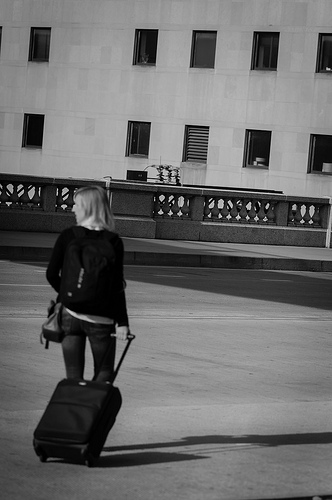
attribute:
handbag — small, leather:
[35, 296, 76, 345]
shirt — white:
[58, 306, 116, 324]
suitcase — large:
[16, 324, 156, 473]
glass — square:
[194, 32, 213, 67]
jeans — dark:
[41, 296, 120, 383]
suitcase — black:
[28, 327, 136, 461]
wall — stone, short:
[1, 170, 330, 248]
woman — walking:
[29, 187, 140, 465]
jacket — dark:
[47, 235, 68, 278]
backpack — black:
[61, 237, 117, 308]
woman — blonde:
[41, 183, 116, 386]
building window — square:
[245, 27, 282, 75]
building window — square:
[185, 28, 217, 70]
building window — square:
[26, 23, 51, 64]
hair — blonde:
[72, 185, 117, 232]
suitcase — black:
[31, 332, 135, 466]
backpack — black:
[57, 224, 121, 328]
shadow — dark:
[89, 432, 320, 466]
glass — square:
[310, 133, 321, 169]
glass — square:
[243, 130, 270, 165]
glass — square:
[129, 122, 150, 158]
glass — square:
[21, 112, 43, 150]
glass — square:
[26, 26, 50, 61]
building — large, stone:
[0, 0, 331, 199]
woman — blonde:
[44, 182, 141, 390]